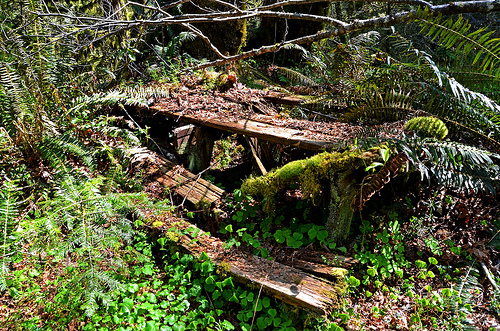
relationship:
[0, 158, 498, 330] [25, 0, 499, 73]
ground under branch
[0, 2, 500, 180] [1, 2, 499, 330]
trees in jungle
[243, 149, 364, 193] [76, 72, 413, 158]
moss growing on board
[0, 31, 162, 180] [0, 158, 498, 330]
fern growing on ground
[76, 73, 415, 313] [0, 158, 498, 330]
table on ground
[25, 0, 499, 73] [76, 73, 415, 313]
branch resting on table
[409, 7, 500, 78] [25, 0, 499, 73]
leaf on branch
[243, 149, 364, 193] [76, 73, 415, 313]
moss growing on table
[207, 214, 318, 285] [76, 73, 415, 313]
shadow on table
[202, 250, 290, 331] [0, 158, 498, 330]
vine growing on ground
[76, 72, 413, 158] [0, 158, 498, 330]
board on ground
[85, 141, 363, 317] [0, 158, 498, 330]
board on ground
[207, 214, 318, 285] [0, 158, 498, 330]
shadow on ground